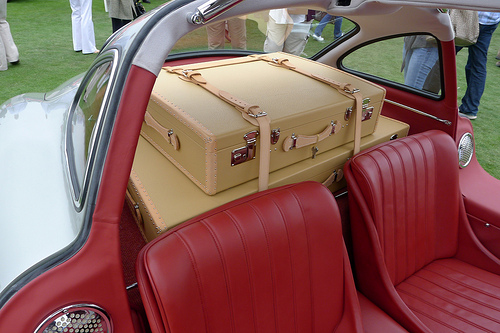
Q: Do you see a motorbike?
A: No, there are no motorcycles.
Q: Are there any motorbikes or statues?
A: No, there are no motorbikes or statues.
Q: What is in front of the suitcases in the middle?
A: The seat is in front of the suitcases.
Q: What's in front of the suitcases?
A: The seat is in front of the suitcases.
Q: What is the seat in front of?
A: The seat is in front of the suitcases.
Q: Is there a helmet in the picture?
A: No, there are no helmets.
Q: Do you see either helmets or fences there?
A: No, there are no helmets or fences.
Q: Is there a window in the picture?
A: Yes, there is a window.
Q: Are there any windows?
A: Yes, there is a window.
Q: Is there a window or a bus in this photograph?
A: Yes, there is a window.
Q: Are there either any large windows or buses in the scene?
A: Yes, there is a large window.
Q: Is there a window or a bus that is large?
A: Yes, the window is large.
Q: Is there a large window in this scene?
A: Yes, there is a large window.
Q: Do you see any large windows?
A: Yes, there is a large window.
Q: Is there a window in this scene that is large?
A: Yes, there is a window that is large.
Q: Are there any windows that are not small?
A: Yes, there is a large window.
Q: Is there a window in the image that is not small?
A: Yes, there is a large window.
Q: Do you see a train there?
A: No, there are no trains.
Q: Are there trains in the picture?
A: No, there are no trains.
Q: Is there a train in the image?
A: No, there are no trains.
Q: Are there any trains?
A: No, there are no trains.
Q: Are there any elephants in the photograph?
A: No, there are no elephants.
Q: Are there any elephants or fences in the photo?
A: No, there are no elephants or fences.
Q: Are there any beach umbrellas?
A: No, there are no beach umbrellas.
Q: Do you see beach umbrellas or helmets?
A: No, there are no beach umbrellas or helmets.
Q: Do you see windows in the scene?
A: Yes, there is a window.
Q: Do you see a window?
A: Yes, there is a window.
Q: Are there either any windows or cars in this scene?
A: Yes, there is a window.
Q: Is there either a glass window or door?
A: Yes, there is a glass window.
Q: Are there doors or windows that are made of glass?
A: Yes, the window is made of glass.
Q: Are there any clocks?
A: No, there are no clocks.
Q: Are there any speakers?
A: Yes, there is a speaker.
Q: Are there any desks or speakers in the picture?
A: Yes, there is a speaker.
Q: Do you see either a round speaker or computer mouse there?
A: Yes, there is a round speaker.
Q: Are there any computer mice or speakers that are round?
A: Yes, the speaker is round.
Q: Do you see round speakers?
A: Yes, there is a round speaker.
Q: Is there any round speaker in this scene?
A: Yes, there is a round speaker.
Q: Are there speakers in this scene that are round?
A: Yes, there is a speaker that is round.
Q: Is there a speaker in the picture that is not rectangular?
A: Yes, there is a round speaker.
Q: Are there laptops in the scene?
A: No, there are no laptops.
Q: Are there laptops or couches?
A: No, there are no laptops or couches.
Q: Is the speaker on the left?
A: Yes, the speaker is on the left of the image.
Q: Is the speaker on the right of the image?
A: No, the speaker is on the left of the image.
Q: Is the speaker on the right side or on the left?
A: The speaker is on the left of the image.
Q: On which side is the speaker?
A: The speaker is on the left of the image.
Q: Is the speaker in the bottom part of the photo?
A: Yes, the speaker is in the bottom of the image.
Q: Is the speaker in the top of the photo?
A: No, the speaker is in the bottom of the image.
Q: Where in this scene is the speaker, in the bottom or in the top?
A: The speaker is in the bottom of the image.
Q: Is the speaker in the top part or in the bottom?
A: The speaker is in the bottom of the image.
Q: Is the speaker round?
A: Yes, the speaker is round.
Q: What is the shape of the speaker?
A: The speaker is round.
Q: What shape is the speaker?
A: The speaker is round.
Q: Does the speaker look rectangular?
A: No, the speaker is round.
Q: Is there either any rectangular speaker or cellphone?
A: No, there is a speaker but it is round.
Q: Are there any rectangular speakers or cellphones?
A: No, there is a speaker but it is round.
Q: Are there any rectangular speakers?
A: No, there is a speaker but it is round.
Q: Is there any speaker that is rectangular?
A: No, there is a speaker but it is round.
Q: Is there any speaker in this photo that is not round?
A: No, there is a speaker but it is round.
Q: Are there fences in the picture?
A: No, there are no fences.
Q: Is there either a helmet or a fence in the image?
A: No, there are no fences or helmets.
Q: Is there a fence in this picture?
A: No, there are no fences.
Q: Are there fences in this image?
A: No, there are no fences.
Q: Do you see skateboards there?
A: No, there are no skateboards.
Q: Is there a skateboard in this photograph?
A: No, there are no skateboards.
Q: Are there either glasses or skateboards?
A: No, there are no skateboards or glasses.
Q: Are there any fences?
A: No, there are no fences.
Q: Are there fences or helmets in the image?
A: No, there are no fences or helmets.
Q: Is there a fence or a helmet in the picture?
A: No, there are no fences or helmets.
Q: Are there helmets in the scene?
A: No, there are no helmets.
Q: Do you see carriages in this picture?
A: No, there are no carriages.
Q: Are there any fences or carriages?
A: No, there are no carriages or fences.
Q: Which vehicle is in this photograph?
A: The vehicle is a car.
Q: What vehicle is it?
A: The vehicle is a car.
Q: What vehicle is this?
A: This is a car.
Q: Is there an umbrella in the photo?
A: No, there are no umbrellas.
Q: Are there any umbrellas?
A: No, there are no umbrellas.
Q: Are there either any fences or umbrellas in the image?
A: No, there are no umbrellas or fences.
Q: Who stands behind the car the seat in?
A: The people stand behind the car.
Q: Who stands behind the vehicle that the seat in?
A: The people stand behind the car.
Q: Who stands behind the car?
A: The people stand behind the car.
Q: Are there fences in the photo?
A: No, there are no fences.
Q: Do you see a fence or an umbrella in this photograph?
A: No, there are no fences or umbrellas.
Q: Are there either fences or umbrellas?
A: No, there are no fences or umbrellas.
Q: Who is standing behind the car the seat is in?
A: The people are standing behind the car.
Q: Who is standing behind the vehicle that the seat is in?
A: The people are standing behind the car.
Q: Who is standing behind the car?
A: The people are standing behind the car.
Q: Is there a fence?
A: No, there are no fences.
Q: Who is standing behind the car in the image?
A: The people are standing behind the car.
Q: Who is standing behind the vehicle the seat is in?
A: The people are standing behind the car.